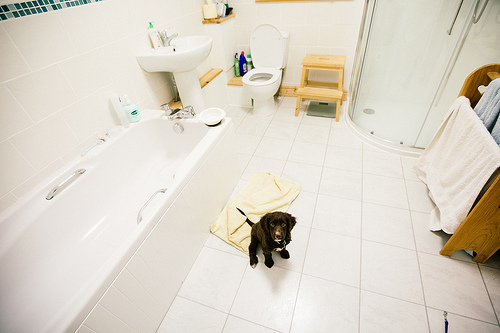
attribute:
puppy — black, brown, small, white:
[237, 207, 297, 269]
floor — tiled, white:
[157, 97, 499, 331]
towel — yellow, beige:
[209, 168, 301, 255]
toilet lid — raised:
[249, 22, 284, 68]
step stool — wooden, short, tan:
[293, 53, 349, 122]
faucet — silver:
[164, 106, 195, 121]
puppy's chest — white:
[270, 239, 289, 254]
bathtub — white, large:
[3, 103, 236, 331]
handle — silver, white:
[43, 167, 85, 200]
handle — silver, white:
[133, 185, 164, 226]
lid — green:
[146, 17, 157, 29]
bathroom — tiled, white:
[3, 2, 498, 332]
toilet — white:
[240, 22, 289, 115]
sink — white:
[137, 31, 215, 108]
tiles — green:
[1, 0, 102, 24]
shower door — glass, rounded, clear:
[346, 0, 480, 149]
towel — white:
[412, 92, 497, 235]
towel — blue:
[472, 77, 498, 142]